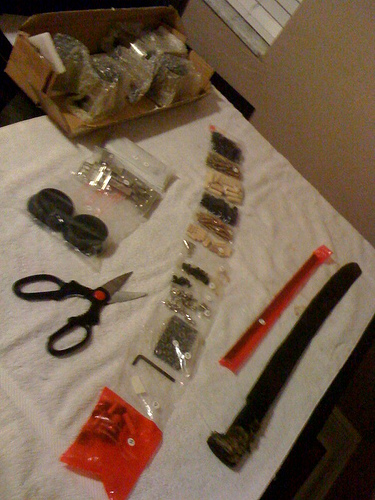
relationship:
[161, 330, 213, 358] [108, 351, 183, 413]
beads in plastic bags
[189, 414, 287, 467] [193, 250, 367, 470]
handle of knife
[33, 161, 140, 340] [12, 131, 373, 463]
items on table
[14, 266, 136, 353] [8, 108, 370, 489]
kitchen scissors on table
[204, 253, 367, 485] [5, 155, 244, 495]
knife on table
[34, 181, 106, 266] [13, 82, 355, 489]
sunglasses on table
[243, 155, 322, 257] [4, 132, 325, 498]
cloth on table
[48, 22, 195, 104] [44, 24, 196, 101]
items in baggies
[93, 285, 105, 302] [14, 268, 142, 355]
dot on scissors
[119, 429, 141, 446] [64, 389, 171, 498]
number on bags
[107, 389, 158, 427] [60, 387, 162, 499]
edge on packet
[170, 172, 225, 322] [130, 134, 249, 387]
parts in packets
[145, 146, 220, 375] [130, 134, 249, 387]
pieces in packets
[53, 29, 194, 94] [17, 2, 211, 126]
items in box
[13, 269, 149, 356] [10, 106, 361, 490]
kitchen scissors in towel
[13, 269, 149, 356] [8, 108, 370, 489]
kitchen scissors on table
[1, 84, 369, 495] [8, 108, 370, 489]
towel over table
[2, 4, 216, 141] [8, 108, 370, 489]
box on table